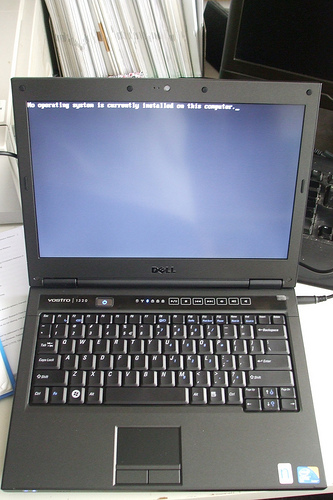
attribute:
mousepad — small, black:
[116, 425, 180, 462]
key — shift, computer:
[248, 369, 292, 384]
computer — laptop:
[9, 72, 327, 492]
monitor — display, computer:
[38, 101, 302, 315]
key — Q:
[56, 337, 75, 353]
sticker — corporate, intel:
[269, 453, 327, 498]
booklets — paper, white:
[44, 0, 203, 77]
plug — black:
[298, 290, 332, 307]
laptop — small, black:
[2, 36, 328, 486]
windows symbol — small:
[297, 463, 320, 486]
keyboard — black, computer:
[30, 305, 297, 410]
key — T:
[125, 337, 142, 352]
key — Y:
[145, 334, 160, 349]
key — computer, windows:
[23, 55, 322, 495]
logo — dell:
[137, 263, 184, 281]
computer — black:
[32, 84, 320, 484]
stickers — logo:
[271, 460, 321, 487]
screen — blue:
[35, 108, 280, 249]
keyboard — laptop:
[18, 317, 298, 414]